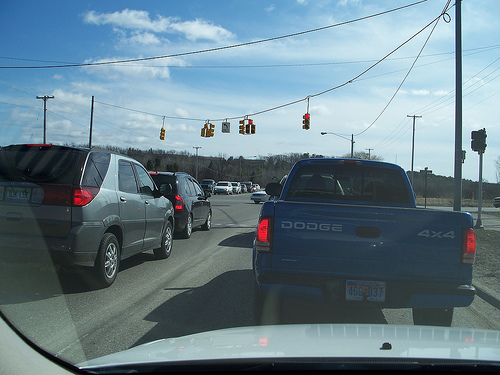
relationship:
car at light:
[1, 145, 175, 288] [305, 113, 310, 118]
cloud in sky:
[0, 1, 498, 183] [4, 2, 494, 153]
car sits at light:
[251, 158, 476, 326] [293, 107, 318, 134]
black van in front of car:
[139, 160, 221, 250] [1, 143, 175, 288]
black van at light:
[139, 160, 221, 250] [305, 113, 310, 118]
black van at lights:
[139, 160, 221, 250] [248, 119, 253, 124]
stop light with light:
[302, 113, 310, 130] [305, 112, 310, 118]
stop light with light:
[302, 113, 310, 130] [303, 124, 308, 129]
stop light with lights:
[292, 105, 325, 137] [186, 86, 284, 154]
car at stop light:
[251, 158, 476, 326] [302, 113, 310, 130]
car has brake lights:
[251, 158, 476, 326] [238, 205, 479, 262]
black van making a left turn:
[144, 170, 213, 238] [245, 186, 286, 216]